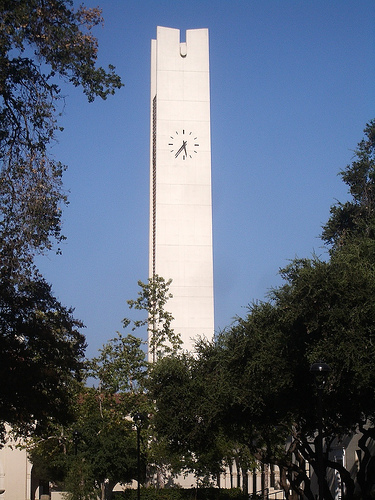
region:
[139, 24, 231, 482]
A tall white monument with a clock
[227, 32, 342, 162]
A cloudless blue sky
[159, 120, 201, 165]
A clock on the front of monument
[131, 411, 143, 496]
A black light post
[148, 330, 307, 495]
Green trees in front of monument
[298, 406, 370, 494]
A white building behind trees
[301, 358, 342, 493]
A tall black light post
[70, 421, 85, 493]
A black light post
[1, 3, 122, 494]
Trees with green leaves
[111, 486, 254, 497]
short green hedges in front of monument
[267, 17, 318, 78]
part of the sky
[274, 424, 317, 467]
part of a branch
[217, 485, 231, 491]
edge of a bush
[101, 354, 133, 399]
part of a top tree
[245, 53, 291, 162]
this is the sky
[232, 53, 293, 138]
the sky is blue in color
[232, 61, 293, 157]
the sky is clear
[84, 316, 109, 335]
the sky has some clouds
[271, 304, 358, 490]
these are some trees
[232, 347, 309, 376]
the leaves are green in color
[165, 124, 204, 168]
this is a clock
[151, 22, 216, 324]
this is a building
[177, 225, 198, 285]
the building is white in color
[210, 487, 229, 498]
the grass is green in color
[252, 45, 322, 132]
The sky is a clear blue.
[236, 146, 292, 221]
The sky is clear.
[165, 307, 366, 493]
Trees are in the picture.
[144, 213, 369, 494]
The trees are in a row.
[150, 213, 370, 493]
The trees have leaves.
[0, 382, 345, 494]
Buildings are in the background.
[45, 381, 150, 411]
A brown roof is in the background.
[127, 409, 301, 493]
The buildings are white.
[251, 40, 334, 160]
The sky is bright.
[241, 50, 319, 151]
The sky is rich blue.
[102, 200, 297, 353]
the tower is white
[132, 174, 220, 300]
the tower is white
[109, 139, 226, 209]
the tower is white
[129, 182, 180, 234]
the tower is white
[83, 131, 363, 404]
the tower is white